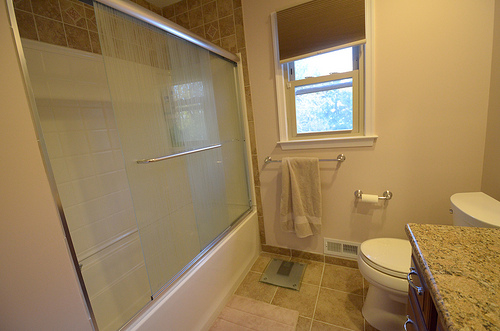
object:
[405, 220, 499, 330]
countertop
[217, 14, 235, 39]
tile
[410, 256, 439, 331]
drawer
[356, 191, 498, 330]
toilet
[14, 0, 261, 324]
door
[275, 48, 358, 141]
window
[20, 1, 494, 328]
wall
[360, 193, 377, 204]
toilet paper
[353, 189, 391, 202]
holder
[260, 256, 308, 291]
panel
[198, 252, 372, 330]
floor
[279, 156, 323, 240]
towel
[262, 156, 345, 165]
rack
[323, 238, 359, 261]
vent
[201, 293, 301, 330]
rug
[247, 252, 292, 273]
tile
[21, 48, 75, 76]
tile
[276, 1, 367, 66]
blind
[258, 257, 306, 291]
scale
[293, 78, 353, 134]
pane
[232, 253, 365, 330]
tile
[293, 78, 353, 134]
tree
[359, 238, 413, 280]
toilet seat